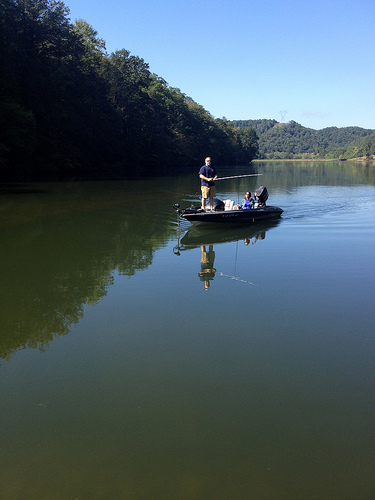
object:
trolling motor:
[255, 184, 270, 203]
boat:
[173, 200, 284, 221]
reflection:
[173, 216, 283, 257]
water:
[0, 159, 372, 500]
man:
[199, 155, 216, 213]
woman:
[242, 191, 255, 210]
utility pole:
[277, 107, 289, 124]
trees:
[0, 0, 261, 167]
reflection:
[198, 244, 217, 291]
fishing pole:
[214, 174, 263, 181]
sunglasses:
[206, 159, 211, 162]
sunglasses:
[245, 193, 251, 197]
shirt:
[198, 165, 217, 188]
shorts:
[201, 186, 217, 199]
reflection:
[1, 167, 213, 358]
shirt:
[241, 200, 254, 208]